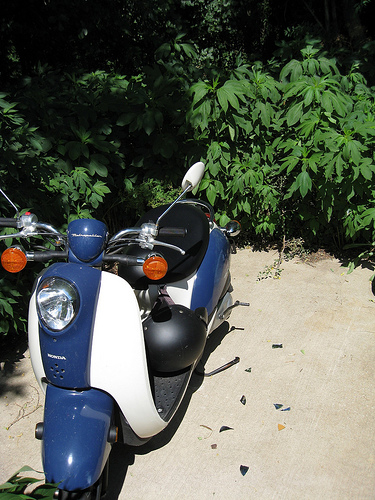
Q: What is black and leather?
A: Bike seat.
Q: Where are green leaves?
A: On bushes.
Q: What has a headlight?
A: The bike.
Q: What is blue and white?
A: Motorbike.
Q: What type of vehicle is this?
A: Motorbike.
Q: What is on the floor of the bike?
A: Helmet.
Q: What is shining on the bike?
A: Sun.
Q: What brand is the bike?
A: Honda.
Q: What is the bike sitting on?
A: Concrete.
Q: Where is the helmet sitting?
A: On the bike.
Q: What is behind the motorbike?
A: Plants.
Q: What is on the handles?
A: Mirrors.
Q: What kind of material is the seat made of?
A: Nylon.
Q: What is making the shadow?
A: The leaves.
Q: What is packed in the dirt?
A: Motorscooter.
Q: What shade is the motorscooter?
A: Blueand white.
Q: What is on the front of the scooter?
A: A light.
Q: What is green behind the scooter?
A: Foliage.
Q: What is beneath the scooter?
A: Concrete.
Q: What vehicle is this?
A: Motor scooter.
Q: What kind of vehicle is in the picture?
A: A scooter.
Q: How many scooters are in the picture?
A: One.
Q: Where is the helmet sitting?
A: The footrest.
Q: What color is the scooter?
A: Blue & white.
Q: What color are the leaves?
A: Green.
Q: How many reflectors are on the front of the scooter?
A: Two.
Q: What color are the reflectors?
A: Orange.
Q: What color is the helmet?
A: Black.